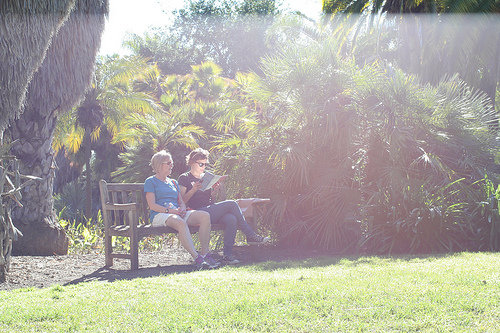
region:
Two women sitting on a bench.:
[145, 148, 272, 268]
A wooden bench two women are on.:
[96, 178, 256, 270]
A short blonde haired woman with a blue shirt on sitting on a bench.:
[145, 148, 220, 268]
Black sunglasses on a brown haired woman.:
[189, 158, 209, 168]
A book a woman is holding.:
[196, 166, 225, 195]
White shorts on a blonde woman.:
[148, 205, 200, 227]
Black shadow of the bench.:
[64, 263, 202, 286]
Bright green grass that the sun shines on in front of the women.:
[6, 255, 499, 330]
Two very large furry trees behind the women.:
[0, 0, 111, 282]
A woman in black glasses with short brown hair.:
[178, 148, 270, 263]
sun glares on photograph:
[3, 0, 499, 332]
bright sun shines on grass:
[1, 250, 498, 327]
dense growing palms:
[231, 0, 498, 238]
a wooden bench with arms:
[98, 174, 260, 271]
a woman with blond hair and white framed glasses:
[131, 148, 178, 181]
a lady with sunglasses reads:
[175, 141, 229, 201]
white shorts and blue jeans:
[147, 194, 264, 264]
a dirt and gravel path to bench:
[0, 243, 321, 285]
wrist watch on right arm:
[158, 205, 176, 215]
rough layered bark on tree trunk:
[0, 95, 64, 225]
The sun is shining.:
[3, 6, 493, 331]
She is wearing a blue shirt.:
[138, 176, 186, 211]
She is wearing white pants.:
[150, 205, 199, 225]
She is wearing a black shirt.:
[176, 169, 221, 211]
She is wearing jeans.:
[207, 200, 261, 246]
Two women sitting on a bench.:
[91, 151, 273, 259]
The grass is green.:
[39, 250, 497, 332]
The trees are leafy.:
[74, 32, 496, 235]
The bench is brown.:
[84, 175, 274, 258]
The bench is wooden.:
[85, 165, 270, 274]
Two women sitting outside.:
[144, 146, 264, 269]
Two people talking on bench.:
[141, 150, 278, 268]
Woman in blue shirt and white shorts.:
[144, 151, 219, 272]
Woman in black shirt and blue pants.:
[177, 136, 268, 266]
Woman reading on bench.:
[178, 143, 266, 265]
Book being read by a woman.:
[197, 172, 224, 193]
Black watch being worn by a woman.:
[160, 203, 170, 215]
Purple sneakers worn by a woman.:
[192, 254, 222, 272]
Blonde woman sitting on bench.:
[142, 149, 221, 269]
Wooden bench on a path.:
[96, 178, 261, 270]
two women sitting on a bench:
[105, 140, 260, 244]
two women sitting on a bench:
[83, 140, 278, 316]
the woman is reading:
[177, 140, 230, 238]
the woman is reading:
[173, 123, 268, 268]